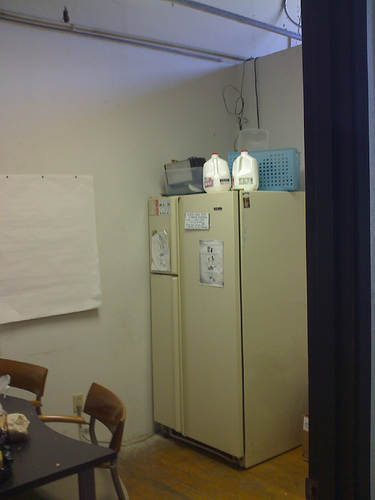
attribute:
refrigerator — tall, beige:
[145, 189, 306, 463]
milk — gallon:
[202, 150, 235, 192]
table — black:
[1, 390, 106, 495]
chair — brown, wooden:
[44, 382, 160, 493]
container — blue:
[228, 148, 303, 192]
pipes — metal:
[181, 5, 301, 41]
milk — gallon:
[234, 148, 255, 191]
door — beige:
[180, 196, 243, 448]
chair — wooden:
[0, 353, 44, 413]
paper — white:
[3, 171, 104, 326]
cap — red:
[241, 150, 247, 153]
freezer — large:
[147, 200, 179, 431]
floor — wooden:
[132, 460, 305, 500]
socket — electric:
[74, 395, 84, 413]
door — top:
[146, 200, 177, 277]